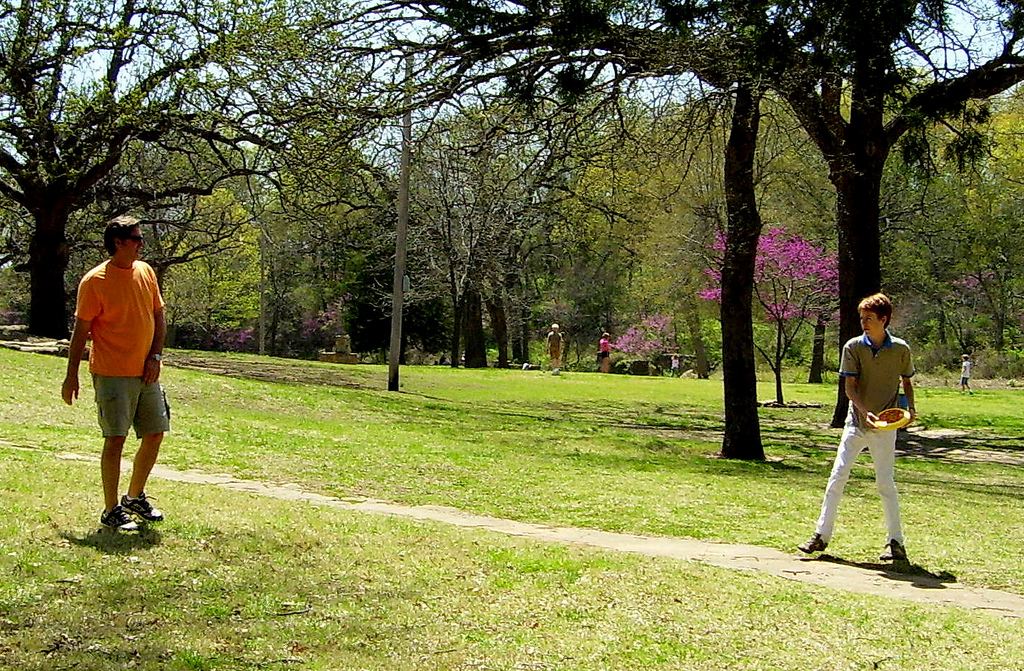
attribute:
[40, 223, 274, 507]
man — standing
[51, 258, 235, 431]
shirt — orange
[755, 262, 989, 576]
man — standing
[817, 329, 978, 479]
shirt — grey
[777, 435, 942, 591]
pants — white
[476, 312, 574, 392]
person — walking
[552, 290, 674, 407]
tree — pine, growing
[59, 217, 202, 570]
man — playing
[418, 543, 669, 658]
grass — short, green, yellow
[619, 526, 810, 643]
grass — yellow, short, green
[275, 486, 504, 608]
grass — green, yellow, short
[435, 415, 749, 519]
grass — short, green, yellow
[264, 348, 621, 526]
grass — yellow, green, short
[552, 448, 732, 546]
grass — short, green, yellow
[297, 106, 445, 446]
pole — tall, gray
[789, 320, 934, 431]
shirt — short sleeve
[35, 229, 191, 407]
shirt — orange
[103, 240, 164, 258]
sunglasses — dark, black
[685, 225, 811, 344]
leaves — purple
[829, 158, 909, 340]
trunk — large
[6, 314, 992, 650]
grass — green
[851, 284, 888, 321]
hair — short, brown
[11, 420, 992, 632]
trail — long, dirt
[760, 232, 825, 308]
flowers — purple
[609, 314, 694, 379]
bush — flowery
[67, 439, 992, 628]
path — bare